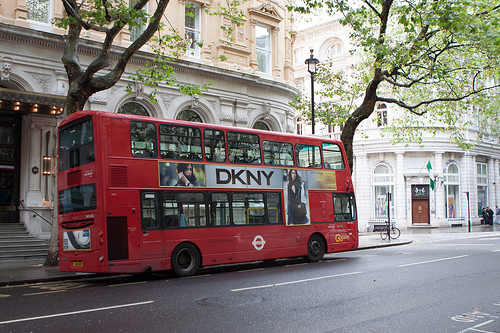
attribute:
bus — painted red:
[58, 110, 352, 247]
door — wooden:
[406, 185, 429, 225]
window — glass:
[131, 127, 156, 156]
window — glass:
[224, 134, 262, 164]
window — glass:
[260, 142, 294, 165]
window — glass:
[332, 194, 356, 224]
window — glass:
[57, 182, 95, 213]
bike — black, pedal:
[378, 220, 399, 240]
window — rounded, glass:
[444, 159, 464, 222]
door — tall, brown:
[2, 111, 23, 226]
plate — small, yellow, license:
[69, 257, 86, 270]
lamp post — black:
[301, 45, 338, 133]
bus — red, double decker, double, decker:
[51, 108, 356, 276]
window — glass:
[297, 145, 324, 166]